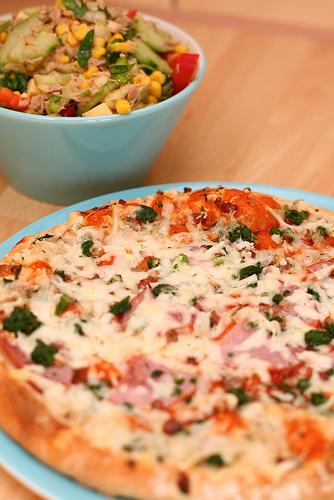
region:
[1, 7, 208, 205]
A small blue bowl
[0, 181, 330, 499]
A blue ceramic plate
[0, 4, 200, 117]
some meat and veggies in a bowl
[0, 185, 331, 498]
A pizza on a plate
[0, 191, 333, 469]
some melted cheese on a pizza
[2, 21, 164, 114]
some corn in a bowl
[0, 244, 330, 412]
some ham on a pizza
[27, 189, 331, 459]
some sauce on a pizza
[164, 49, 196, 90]
A red pepper in a bowl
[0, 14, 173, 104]
some cucumber in a bowl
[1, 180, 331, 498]
pizza on a blue plate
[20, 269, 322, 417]
ham topping on pizza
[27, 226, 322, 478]
white cheese on the pizza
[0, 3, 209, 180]
salad in a blue bowl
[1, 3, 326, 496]
blue plate and bowl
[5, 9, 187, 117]
corn in the blue bowl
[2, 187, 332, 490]
crust of the pizza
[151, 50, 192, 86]
chunk of tomato in the blue bowl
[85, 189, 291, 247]
sauce on the pizza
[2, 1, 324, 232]
table bowl and plate are on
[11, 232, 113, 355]
Portion of a pizza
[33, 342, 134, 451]
Portion of a pizza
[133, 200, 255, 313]
Portion of a pizza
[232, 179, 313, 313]
Portion of a pizza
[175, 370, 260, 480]
Portion of a pizza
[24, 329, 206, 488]
Portion of a pizza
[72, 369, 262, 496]
Portion of a pizza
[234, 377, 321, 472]
Portion of a pizza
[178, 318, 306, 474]
Portion of a pizza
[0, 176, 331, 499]
round blue plate holding pizza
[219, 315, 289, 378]
piece of canadian bacon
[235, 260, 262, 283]
piece of spinach topping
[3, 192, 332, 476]
melted white mozzarella cheese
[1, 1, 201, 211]
bowl of vegetable salad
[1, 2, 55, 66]
slices of green cucumber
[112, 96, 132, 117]
kernel of corn atop salad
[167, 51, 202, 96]
slice of tomato in salad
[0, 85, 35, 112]
baby carrot in salad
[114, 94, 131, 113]
a golden kernel of corn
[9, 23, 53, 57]
chopped green cucumbers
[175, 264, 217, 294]
white cheese melted on a pizza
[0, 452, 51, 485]
a light blue plate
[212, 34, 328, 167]
a light colored wooden table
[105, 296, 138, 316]
a sprig of green onion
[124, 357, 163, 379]
pink chunks of ham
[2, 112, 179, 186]
a light blue ceramic bowl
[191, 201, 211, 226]
a bit of red tomato sauce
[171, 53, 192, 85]
a juicy chunk of red tomato